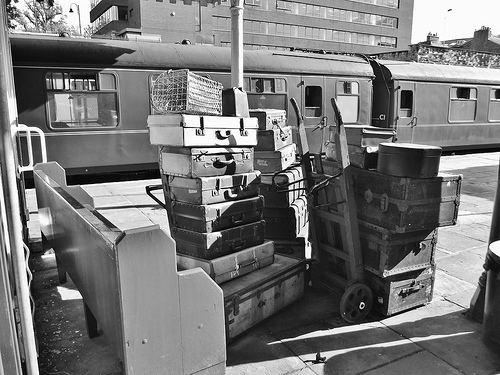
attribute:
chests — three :
[352, 144, 467, 319]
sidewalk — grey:
[18, 147, 498, 370]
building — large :
[88, 0, 415, 62]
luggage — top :
[135, 119, 321, 340]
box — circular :
[372, 107, 450, 214]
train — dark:
[56, 17, 485, 168]